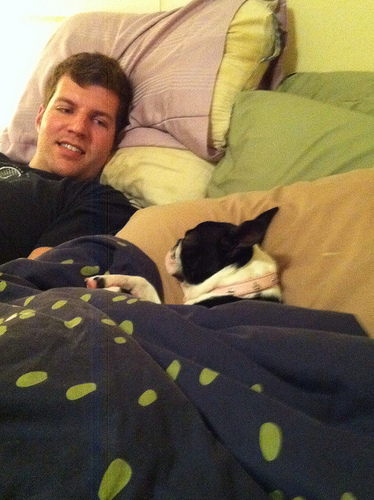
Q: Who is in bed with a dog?
A: A man.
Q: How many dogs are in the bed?
A: One.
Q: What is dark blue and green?
A: Blankets.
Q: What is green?
A: Two pillows.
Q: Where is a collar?
A: Around dog's neck.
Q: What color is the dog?
A: White and black.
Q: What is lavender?
A: Pillowcase.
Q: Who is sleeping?
A: The dog.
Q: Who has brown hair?
A: The man.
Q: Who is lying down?
A: Dog and man.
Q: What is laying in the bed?
A: Dog.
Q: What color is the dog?
A: Black and white.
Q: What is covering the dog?
A: Blanket.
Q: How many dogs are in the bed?
A: One.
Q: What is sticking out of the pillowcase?
A: Pillow.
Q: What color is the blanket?
A: Blue.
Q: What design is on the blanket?
A: Leaves.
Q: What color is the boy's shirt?
A: Black.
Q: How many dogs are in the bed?
A: One.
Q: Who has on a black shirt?
A: The man.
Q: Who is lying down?
A: Man and dog.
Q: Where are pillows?
A: On the bed.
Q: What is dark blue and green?
A: Blanket.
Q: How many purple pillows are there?
A: One.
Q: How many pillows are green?
A: Two.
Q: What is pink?
A: Dog's collar.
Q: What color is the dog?
A: White and black.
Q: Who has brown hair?
A: A man.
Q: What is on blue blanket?
A: Green spots.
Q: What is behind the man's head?
A: Pillow.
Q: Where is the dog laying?
A: On the bed.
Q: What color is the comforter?
A: Blue and green.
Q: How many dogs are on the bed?
A: One.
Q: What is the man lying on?
A: A bed.